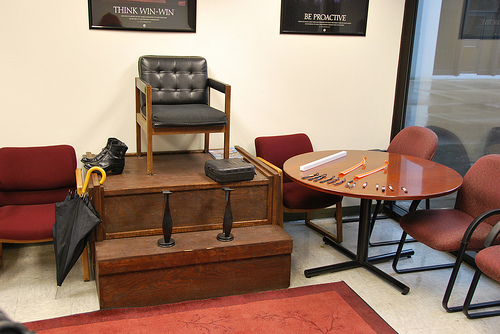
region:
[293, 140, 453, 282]
table near the window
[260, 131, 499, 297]
chairs near the table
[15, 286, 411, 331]
rug on the floor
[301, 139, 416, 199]
items on the table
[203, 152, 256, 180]
container on the shelf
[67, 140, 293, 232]
shelf next to table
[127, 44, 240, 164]
chair on the shelf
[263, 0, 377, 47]
image on the wall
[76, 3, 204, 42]
image on the wall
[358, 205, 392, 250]
part of a stand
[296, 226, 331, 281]
part of a floor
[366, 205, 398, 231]
part of a stand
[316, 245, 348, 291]
aprt of a floor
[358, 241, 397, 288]
part of a stand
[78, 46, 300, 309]
this is a shoeshine stand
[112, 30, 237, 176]
this is a chair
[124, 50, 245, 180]
the chair is made of wood and leather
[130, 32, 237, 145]
the seat and backrest are black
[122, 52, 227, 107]
the backrest is black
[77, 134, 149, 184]
black leather boots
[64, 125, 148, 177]
a pair of black boots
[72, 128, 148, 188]
pair of leather boots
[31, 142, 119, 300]
this is a black umbrella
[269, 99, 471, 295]
the tabletop is round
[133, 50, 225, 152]
this is a chair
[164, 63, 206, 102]
the chair is leather like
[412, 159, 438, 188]
this is a chair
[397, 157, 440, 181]
the chair is wooden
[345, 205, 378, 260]
this is the stem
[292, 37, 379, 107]
this is the wall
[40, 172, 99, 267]
this is an umbrella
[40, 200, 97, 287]
the umbrella is black in color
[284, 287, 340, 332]
this is a mat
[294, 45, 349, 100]
the wall is white in color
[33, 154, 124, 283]
black umbrella with wood handle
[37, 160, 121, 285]
black umbrella with wood handle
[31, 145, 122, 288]
black umbrella with wood handle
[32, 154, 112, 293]
black umbrella with wood handle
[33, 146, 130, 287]
black umbrella with wood handle